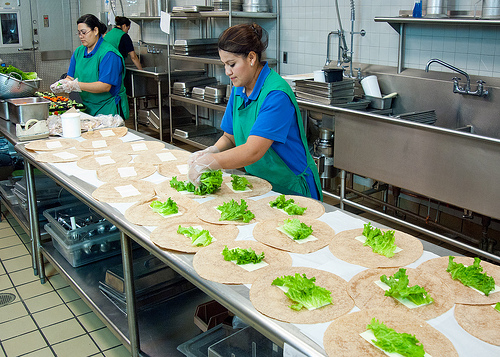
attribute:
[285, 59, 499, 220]
sink — metal, stainless steel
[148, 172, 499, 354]
lettuce — green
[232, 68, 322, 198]
apron — green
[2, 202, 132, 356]
tiles — beige, white, tiled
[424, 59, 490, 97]
faucet — metal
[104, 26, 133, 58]
shirt — black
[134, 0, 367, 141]
pans — metal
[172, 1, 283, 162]
rack — metal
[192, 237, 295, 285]
tortilla — large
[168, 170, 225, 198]
letuce — green